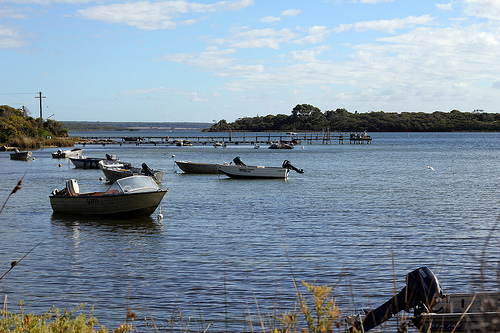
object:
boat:
[40, 167, 180, 227]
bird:
[421, 154, 441, 174]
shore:
[0, 284, 499, 331]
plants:
[0, 285, 18, 333]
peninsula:
[198, 103, 499, 139]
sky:
[1, 1, 499, 122]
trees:
[330, 105, 351, 130]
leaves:
[303, 104, 310, 109]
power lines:
[41, 100, 55, 115]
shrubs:
[1, 117, 17, 129]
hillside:
[1, 91, 78, 156]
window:
[113, 171, 165, 201]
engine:
[47, 173, 81, 203]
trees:
[390, 108, 411, 132]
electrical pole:
[33, 87, 49, 139]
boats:
[168, 155, 247, 180]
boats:
[268, 137, 282, 157]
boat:
[206, 149, 305, 189]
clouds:
[402, 42, 493, 94]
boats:
[62, 147, 128, 170]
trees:
[446, 108, 464, 129]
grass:
[242, 260, 373, 331]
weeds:
[64, 304, 93, 332]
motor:
[276, 157, 308, 178]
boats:
[91, 152, 170, 187]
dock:
[58, 126, 384, 152]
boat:
[2, 139, 40, 168]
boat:
[369, 263, 500, 333]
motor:
[342, 258, 458, 331]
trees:
[290, 99, 323, 130]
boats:
[43, 140, 92, 163]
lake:
[0, 127, 500, 332]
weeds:
[19, 306, 46, 331]